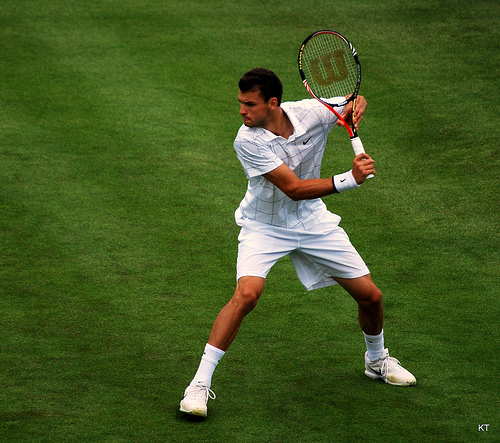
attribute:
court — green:
[37, 72, 198, 251]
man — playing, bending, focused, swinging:
[211, 42, 403, 299]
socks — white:
[188, 346, 231, 373]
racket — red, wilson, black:
[295, 32, 391, 149]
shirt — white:
[256, 137, 331, 215]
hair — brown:
[244, 68, 271, 87]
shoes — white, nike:
[365, 364, 418, 389]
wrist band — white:
[329, 167, 364, 196]